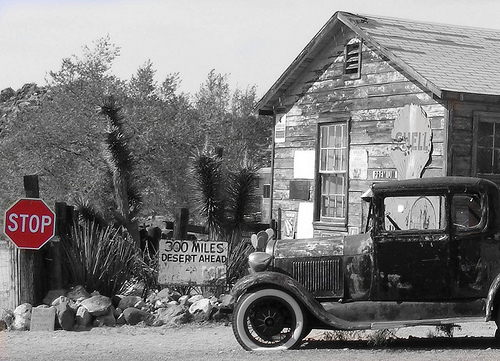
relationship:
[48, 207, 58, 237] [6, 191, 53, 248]
border on sign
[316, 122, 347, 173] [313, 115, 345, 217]
bars on window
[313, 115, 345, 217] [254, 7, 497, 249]
window on house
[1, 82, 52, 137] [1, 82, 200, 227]
rocks on hill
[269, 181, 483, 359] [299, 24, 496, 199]
car by house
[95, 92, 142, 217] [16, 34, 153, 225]
needles on tree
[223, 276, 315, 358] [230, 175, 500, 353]
tire on car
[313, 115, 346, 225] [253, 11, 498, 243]
window on building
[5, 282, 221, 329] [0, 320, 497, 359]
rocks on ground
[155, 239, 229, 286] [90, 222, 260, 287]
desert sign on fence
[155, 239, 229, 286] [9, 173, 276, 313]
desert sign on fence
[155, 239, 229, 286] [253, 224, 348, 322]
desert sign on fence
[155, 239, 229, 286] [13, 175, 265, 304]
desert sign on fence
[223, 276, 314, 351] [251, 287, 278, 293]
tire with wall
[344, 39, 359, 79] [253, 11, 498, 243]
attic vent in building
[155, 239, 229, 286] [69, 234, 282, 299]
desert sign in brush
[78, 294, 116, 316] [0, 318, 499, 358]
rock line road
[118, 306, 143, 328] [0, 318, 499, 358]
rock line road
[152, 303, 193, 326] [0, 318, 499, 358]
rock line road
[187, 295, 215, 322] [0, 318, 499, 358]
rock line road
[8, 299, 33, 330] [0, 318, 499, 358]
rock line road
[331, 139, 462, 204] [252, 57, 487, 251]
sign on building